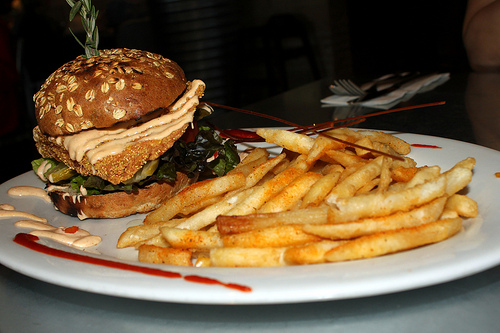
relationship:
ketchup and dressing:
[12, 231, 251, 295] [2, 203, 105, 251]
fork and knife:
[337, 74, 405, 98] [347, 69, 435, 107]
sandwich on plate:
[27, 45, 231, 221] [0, 126, 499, 304]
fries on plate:
[118, 130, 476, 263] [0, 126, 499, 304]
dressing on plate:
[2, 203, 105, 251] [0, 126, 499, 304]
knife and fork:
[347, 69, 435, 107] [337, 74, 405, 98]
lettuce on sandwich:
[154, 102, 238, 176] [27, 45, 231, 221]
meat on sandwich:
[34, 79, 209, 186] [27, 45, 231, 221]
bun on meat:
[31, 47, 189, 137] [34, 79, 209, 186]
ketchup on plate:
[12, 231, 251, 295] [0, 126, 499, 304]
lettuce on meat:
[154, 102, 238, 176] [34, 79, 209, 186]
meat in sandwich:
[34, 79, 209, 186] [27, 45, 231, 221]